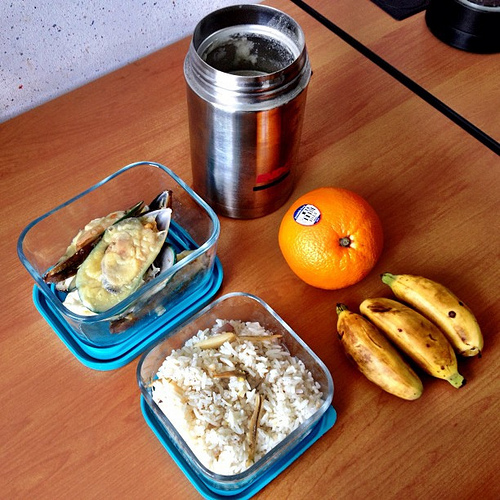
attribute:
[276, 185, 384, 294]
orange — large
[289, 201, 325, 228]
sticker — blue, white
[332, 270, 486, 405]
bananas — yellow, overripe, brown, small, ripe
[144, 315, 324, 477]
rice — white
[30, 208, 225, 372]
lid — blue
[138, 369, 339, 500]
lid — blue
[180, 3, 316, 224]
flask — metallic, silver, for drinking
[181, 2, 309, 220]
container — metal, stainless steel, silver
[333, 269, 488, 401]
plantains — ripe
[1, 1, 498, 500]
table — wood, wood grain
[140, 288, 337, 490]
container — square, glass, small, clear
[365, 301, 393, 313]
mark — dark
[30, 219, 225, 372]
cover — plastic, blue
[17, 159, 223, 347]
container — rectangular, small, clear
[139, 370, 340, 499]
cover — plastic, blue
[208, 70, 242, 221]
reflection — light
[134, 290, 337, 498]
dish — open, glass, square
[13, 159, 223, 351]
dish — open, rectangular, glass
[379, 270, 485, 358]
banana — small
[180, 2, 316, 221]
thermos — metal, thick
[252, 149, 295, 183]
lettering — red